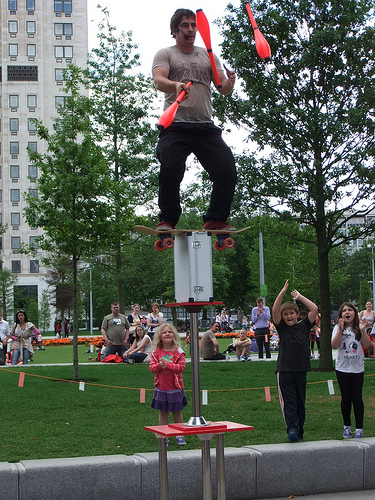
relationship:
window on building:
[55, 0, 73, 14] [1, 0, 91, 336]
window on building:
[54, 24, 72, 38] [1, 0, 91, 336]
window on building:
[55, 46, 73, 60] [1, 0, 91, 336]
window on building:
[55, 69, 74, 82] [1, 0, 91, 336]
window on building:
[55, 98, 73, 112] [1, 0, 91, 336]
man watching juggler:
[101, 302, 130, 363] [153, 8, 240, 233]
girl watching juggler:
[149, 322, 187, 447] [153, 8, 240, 233]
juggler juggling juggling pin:
[153, 8, 240, 233] [244, 2, 271, 61]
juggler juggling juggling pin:
[153, 8, 240, 233] [196, 9, 223, 88]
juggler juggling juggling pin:
[153, 8, 240, 233] [158, 80, 192, 127]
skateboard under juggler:
[133, 225, 252, 250] [153, 8, 240, 233]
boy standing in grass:
[272, 278, 319, 442] [1, 329, 374, 463]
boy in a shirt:
[272, 278, 319, 442] [270, 315, 316, 373]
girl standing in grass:
[332, 302, 372, 439] [1, 329, 374, 463]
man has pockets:
[101, 302, 130, 363] [107, 343, 128, 348]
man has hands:
[101, 302, 130, 363] [107, 340, 128, 345]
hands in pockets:
[107, 340, 128, 345] [107, 343, 128, 348]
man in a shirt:
[251, 297, 274, 357] [252, 307, 273, 329]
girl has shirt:
[149, 322, 187, 447] [157, 348, 175, 390]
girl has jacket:
[149, 322, 187, 447] [150, 345, 186, 392]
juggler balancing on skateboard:
[153, 8, 240, 233] [133, 225, 252, 250]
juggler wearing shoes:
[153, 8, 240, 233] [157, 219, 236, 231]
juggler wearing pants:
[153, 8, 240, 233] [157, 122, 238, 225]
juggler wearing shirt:
[153, 8, 240, 233] [152, 45, 225, 124]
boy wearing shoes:
[272, 278, 319, 442] [288, 430, 304, 442]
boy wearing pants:
[272, 278, 319, 442] [277, 370, 307, 435]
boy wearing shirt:
[272, 278, 319, 442] [270, 315, 316, 373]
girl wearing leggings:
[332, 302, 372, 439] [335, 369, 365, 427]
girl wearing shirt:
[332, 302, 372, 439] [331, 322, 365, 374]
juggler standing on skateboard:
[153, 8, 240, 233] [133, 225, 252, 250]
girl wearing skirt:
[149, 322, 187, 447] [151, 387, 189, 410]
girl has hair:
[149, 322, 187, 447] [153, 322, 182, 353]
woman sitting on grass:
[121, 325, 154, 363] [1, 329, 374, 463]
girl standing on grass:
[149, 322, 187, 447] [1, 329, 374, 463]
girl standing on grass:
[332, 302, 372, 439] [1, 329, 374, 463]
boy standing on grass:
[272, 278, 319, 442] [1, 329, 374, 463]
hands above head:
[284, 279, 302, 300] [281, 302, 299, 326]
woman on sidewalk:
[121, 325, 154, 363] [1, 349, 374, 370]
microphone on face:
[175, 28, 188, 40] [179, 16, 197, 44]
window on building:
[27, 0, 37, 12] [1, 0, 91, 336]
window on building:
[28, 21, 36, 34] [1, 0, 91, 336]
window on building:
[28, 43, 37, 58] [1, 0, 91, 336]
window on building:
[28, 95, 38, 109] [1, 0, 91, 336]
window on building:
[28, 143, 38, 157] [1, 0, 91, 336]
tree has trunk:
[23, 55, 136, 380] [71, 98, 80, 383]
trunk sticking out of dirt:
[71, 98, 80, 383] [52, 378, 98, 384]